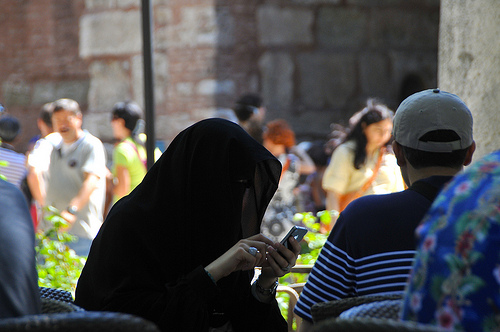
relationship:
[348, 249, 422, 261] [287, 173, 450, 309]
stripe on shirt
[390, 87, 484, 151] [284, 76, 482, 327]
hat on man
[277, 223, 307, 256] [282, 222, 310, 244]
hand holding cellphone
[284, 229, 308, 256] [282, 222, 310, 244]
finger on cellphone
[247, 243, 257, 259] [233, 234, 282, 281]
ring on hand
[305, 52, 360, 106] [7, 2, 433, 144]
stones on wall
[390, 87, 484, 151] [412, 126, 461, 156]
hat has strap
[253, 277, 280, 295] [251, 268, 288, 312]
watch on wrist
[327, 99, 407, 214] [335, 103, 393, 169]
woman has hair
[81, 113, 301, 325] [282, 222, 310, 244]
person has cellphone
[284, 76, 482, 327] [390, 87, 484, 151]
man wearing hat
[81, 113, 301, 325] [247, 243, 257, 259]
person has ring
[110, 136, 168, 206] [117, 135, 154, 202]
man has shirt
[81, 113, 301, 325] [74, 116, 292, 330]
person wearing clothing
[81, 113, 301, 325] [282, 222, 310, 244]
person holding cellphone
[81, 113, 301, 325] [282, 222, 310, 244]
person looking at cellphone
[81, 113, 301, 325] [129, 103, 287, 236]
person covering head